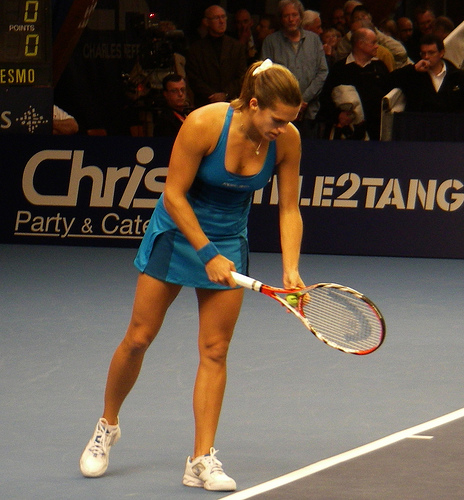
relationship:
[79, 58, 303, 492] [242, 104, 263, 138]
woman has neck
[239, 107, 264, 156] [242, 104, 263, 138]
necklace around neck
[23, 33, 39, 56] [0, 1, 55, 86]
points on scoreboard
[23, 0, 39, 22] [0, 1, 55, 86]
points on scoreboard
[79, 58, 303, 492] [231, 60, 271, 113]
woman with ponytail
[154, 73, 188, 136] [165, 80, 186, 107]
man has face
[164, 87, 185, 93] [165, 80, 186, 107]
glasses on face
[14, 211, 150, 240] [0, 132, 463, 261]
writing on wall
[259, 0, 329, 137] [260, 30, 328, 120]
man in shirt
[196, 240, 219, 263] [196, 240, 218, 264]
wristband on wrist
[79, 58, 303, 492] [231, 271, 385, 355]
woman holding racket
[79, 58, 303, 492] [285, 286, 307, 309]
woman holding tennis ball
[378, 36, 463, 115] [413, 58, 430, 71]
man with hand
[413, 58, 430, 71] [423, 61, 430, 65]
hand to mouth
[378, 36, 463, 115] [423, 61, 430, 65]
man with mouth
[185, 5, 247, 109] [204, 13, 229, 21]
man wearing glasses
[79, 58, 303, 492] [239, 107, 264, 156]
woman wearing necklace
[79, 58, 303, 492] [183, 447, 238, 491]
woman wearing sneaker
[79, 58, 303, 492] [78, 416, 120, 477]
woman wearing sneaker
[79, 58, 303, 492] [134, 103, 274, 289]
woman wearing outfit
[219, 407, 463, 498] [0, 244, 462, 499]
line on tennis court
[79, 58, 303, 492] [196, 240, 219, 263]
woman wearing wristband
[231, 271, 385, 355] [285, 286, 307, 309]
racket with tennis ball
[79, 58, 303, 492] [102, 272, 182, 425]
woman has leg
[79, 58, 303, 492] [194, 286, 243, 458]
woman has leg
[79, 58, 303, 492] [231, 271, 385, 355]
woman with racket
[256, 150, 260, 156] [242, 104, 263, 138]
locket around neck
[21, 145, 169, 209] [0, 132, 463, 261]
writing on wall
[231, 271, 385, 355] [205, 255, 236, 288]
racket in hand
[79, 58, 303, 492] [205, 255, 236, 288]
woman has hand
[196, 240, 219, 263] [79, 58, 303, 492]
wristband on woman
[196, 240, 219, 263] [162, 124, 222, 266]
wristband on arm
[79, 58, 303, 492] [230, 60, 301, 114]
woman has hair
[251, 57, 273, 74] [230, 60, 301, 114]
headband on hair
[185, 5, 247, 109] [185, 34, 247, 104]
man wearing blazer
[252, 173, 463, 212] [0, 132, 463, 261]
writing on wall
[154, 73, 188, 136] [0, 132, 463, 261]
man near wall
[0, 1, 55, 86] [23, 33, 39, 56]
scoreboard with points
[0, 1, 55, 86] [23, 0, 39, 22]
scoreboard with points